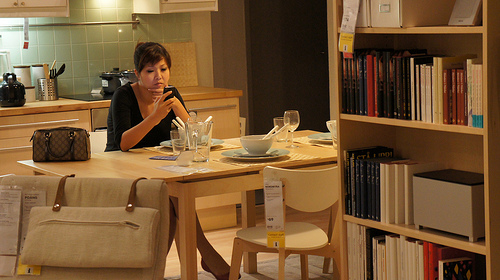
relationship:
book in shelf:
[361, 52, 377, 116] [331, 23, 495, 133]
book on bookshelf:
[422, 239, 429, 277] [327, 0, 500, 280]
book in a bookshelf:
[380, 162, 392, 230] [327, 0, 500, 280]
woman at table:
[97, 39, 214, 154] [13, 120, 367, 242]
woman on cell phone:
[97, 39, 214, 154] [163, 85, 176, 104]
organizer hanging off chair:
[21, 174, 158, 268] [0, 173, 169, 278]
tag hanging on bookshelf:
[335, 24, 357, 59] [327, 0, 499, 278]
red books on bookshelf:
[365, 53, 380, 115] [327, 0, 500, 280]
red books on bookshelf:
[442, 67, 465, 124] [327, 0, 500, 280]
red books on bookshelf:
[424, 242, 442, 279] [327, 0, 500, 280]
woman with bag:
[97, 39, 214, 154] [30, 127, 91, 164]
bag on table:
[30, 127, 91, 164] [14, 129, 337, 279]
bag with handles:
[20, 175, 160, 270] [43, 175, 149, 203]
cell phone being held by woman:
[160, 83, 178, 113] [107, 37, 233, 278]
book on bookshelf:
[409, 57, 416, 119] [327, 0, 500, 280]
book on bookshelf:
[414, 61, 419, 118] [327, 0, 500, 280]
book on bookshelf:
[464, 56, 471, 125] [327, 0, 500, 280]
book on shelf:
[470, 64, 478, 131] [343, 107, 485, 132]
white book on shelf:
[419, 65, 430, 123] [339, 110, 486, 136]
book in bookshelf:
[392, 161, 424, 235] [327, 0, 500, 280]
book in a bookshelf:
[436, 259, 483, 280] [327, 0, 500, 280]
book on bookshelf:
[425, 66, 432, 121] [327, 0, 500, 280]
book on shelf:
[403, 45, 446, 134] [339, 110, 486, 136]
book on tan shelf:
[404, 164, 412, 225] [322, 0, 498, 277]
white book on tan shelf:
[392, 162, 401, 227] [322, 0, 498, 277]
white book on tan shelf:
[377, 164, 387, 220] [322, 0, 498, 277]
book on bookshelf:
[381, 159, 383, 222] [327, 0, 500, 280]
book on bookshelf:
[386, 158, 391, 218] [327, 0, 500, 280]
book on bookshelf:
[396, 161, 401, 216] [327, 0, 500, 280]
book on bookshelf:
[406, 161, 410, 218] [327, 0, 500, 280]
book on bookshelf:
[422, 64, 424, 112] [327, 0, 500, 280]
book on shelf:
[404, 164, 412, 225] [331, 23, 495, 133]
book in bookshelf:
[380, 162, 392, 230] [327, 0, 500, 280]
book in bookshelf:
[422, 239, 429, 277] [327, 0, 500, 280]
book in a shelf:
[428, 246, 441, 278] [345, 216, 483, 278]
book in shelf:
[431, 250, 484, 278] [345, 216, 483, 278]